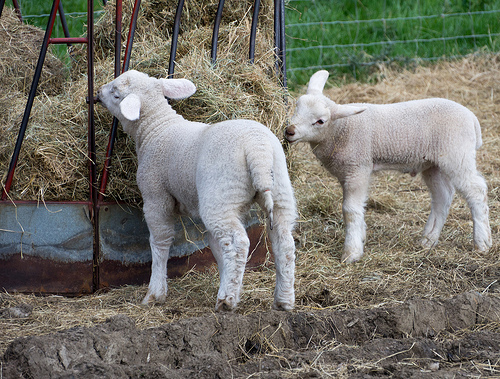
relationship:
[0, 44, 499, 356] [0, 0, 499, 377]
hay on ground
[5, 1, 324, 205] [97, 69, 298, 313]
hay on baby lamb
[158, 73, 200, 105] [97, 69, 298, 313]
lamb ear of baby lamb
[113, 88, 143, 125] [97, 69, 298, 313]
lamb ear of baby lamb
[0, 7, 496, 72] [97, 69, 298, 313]
fence behind baby lamb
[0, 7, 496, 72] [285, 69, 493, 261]
fence behind lamb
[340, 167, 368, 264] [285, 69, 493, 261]
leg of lamb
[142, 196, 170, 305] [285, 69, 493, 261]
leg of lamb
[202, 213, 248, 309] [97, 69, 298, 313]
leg of baby lamb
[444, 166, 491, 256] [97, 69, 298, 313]
leg of baby lamb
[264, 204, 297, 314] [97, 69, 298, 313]
leg of baby lamb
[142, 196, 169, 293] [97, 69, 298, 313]
leg of baby lamb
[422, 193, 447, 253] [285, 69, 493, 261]
leg of lamb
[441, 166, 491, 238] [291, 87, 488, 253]
leg of lamb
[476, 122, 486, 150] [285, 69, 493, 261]
tail of lamb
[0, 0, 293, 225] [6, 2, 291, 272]
food inside of feeder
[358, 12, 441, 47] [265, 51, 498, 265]
grass next to lamb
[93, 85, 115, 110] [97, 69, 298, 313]
nose on face of baby lamb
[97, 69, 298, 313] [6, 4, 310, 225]
baby lamb eating food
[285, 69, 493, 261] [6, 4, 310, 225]
lamb eating food